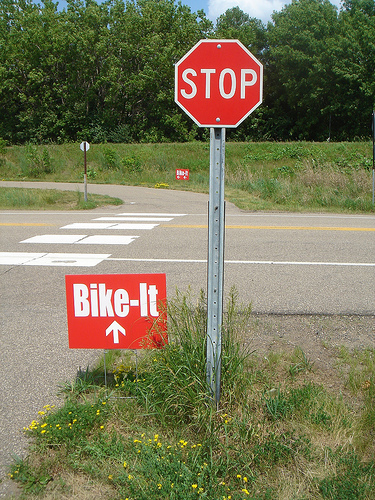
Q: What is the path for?
A: Bicyclists.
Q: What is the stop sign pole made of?
A: Metal.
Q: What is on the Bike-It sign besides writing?
A: An arrow.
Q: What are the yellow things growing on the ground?
A: Flowers.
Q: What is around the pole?
A: Grass.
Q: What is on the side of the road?
A: Trees.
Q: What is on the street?
A: White lines.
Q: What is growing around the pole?
A: Tall grass.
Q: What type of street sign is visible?
A: A stop sign.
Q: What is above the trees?
A: The sky.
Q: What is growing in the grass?
A: Yellow flowers.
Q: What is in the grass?
A: Flowers.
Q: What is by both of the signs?
A: Grass.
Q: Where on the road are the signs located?
A: At a street crossing.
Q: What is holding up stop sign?
A: Gray post.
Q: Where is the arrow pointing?
A: Up.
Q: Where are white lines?
A: On the road.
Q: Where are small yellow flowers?
A: In the grass.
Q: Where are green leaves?
A: On trees.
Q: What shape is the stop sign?
A: Octagonal.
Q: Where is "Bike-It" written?
A: On sign.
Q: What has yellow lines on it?
A: A road.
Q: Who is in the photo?
A: Nobody.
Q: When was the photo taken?
A: Daytime.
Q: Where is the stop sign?
A: On the street corner.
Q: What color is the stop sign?
A: Red.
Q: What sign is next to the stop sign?
A: "Bike-It".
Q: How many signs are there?
A: Four.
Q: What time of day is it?
A: Afternoon.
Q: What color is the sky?
A: Blue.